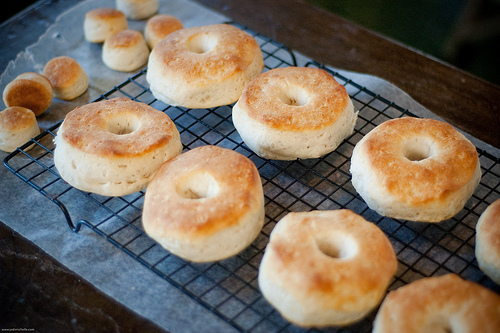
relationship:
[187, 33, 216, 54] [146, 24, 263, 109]
hole in biscuit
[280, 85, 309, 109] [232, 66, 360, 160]
hole in biscuit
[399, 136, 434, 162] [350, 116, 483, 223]
hole in biscuit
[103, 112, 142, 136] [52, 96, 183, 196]
hole in biscuit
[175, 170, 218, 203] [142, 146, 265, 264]
hole in biscuit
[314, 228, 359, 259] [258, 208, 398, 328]
hole in biscuit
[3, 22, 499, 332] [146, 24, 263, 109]
rack under biscuit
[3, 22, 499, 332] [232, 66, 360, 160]
rack under biscuit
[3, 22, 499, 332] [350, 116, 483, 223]
rack under biscuit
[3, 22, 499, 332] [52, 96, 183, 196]
rack under biscuit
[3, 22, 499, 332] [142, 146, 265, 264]
rack under biscuit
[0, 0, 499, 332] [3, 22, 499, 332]
paper under rack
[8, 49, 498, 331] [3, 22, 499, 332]
area under rack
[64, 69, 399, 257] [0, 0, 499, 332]
wrinkle in paper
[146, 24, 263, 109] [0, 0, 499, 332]
biscuit on paper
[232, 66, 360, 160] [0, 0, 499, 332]
biscuit on paper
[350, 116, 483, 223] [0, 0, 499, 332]
biscuit on paper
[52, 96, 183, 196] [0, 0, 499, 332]
biscuit on paper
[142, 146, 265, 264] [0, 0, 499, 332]
biscuit on paper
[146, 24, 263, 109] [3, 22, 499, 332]
biscuit on rack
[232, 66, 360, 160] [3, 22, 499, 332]
biscuit on rack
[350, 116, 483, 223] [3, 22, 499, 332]
biscuit on rack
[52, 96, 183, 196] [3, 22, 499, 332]
biscuit on rack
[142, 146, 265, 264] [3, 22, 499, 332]
biscuit on rack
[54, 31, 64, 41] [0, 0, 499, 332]
hole in paper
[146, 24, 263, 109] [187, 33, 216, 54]
biscuit has hole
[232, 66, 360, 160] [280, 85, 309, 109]
biscuit has hole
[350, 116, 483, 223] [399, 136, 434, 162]
biscuit has hole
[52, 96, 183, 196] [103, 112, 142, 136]
biscuit has hole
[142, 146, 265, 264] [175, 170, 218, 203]
biscuit has hole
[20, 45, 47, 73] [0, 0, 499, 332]
tear in paper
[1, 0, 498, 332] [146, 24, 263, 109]
table under biscuit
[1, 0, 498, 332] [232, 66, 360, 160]
table under biscuit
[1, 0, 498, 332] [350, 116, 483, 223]
table under biscuit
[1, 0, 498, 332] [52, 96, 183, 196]
table under biscuit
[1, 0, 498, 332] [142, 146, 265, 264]
table under biscuit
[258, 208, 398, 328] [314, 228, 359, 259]
biscuit has hole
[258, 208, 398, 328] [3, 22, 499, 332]
biscuit on rack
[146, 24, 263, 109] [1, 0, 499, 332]
biscuit in picture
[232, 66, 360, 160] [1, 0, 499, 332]
biscuit in picture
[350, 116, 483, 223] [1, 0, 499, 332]
biscuit in picture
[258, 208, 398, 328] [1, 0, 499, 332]
biscuit in picture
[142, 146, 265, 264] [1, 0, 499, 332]
biscuit in picture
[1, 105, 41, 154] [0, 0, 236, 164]
ball on side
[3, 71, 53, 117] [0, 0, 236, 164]
ball on side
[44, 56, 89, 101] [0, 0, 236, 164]
ball on side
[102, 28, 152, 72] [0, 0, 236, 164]
ball on side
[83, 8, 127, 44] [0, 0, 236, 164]
ball on side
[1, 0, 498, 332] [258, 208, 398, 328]
table under biscuit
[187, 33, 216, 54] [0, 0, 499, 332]
hole on paper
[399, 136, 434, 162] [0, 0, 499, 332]
hole on paper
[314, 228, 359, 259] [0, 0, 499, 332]
hole on paper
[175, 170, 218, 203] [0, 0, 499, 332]
hole on paper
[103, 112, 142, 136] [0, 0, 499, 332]
hole on paper